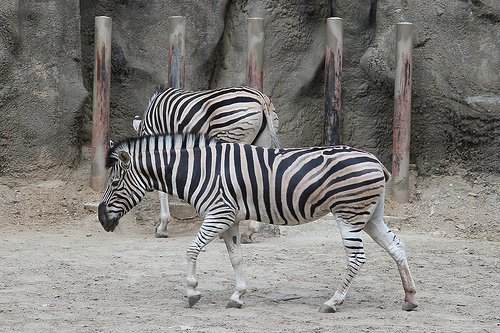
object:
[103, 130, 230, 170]
mane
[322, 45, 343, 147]
paint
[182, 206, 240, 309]
legs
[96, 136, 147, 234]
head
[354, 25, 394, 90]
rocktip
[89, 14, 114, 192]
grey pole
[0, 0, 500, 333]
enclosure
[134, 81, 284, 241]
zebra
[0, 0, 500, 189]
wall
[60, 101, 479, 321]
zebra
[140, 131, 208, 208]
neck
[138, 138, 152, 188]
stripe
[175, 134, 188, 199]
stripe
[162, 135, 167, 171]
stripe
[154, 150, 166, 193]
stripe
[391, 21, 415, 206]
pole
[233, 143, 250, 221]
stripes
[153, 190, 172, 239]
leg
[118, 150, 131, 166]
ear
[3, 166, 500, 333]
ground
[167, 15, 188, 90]
pole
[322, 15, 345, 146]
pole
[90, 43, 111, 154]
marking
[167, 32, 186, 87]
marking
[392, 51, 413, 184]
marking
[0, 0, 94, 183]
boulder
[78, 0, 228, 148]
boulder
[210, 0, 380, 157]
boulder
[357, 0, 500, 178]
boulder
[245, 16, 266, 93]
pole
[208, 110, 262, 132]
lines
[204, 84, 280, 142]
rear